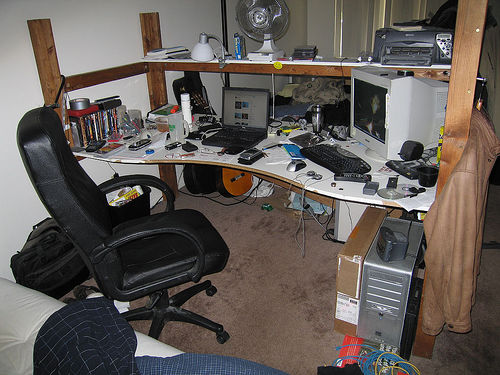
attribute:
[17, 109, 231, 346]
chair — black, leather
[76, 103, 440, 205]
desk — multileveled, white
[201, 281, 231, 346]
wheels — black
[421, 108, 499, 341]
brown jacket — hanging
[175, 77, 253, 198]
guitar — brown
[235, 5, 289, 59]
fan — white, small, silver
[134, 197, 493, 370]
carpet — brown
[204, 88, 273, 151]
laptop — open, small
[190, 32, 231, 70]
white lamp — clipped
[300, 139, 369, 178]
keyboard — black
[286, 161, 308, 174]
mouse — black, gray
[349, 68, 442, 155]
monitor — white, large, old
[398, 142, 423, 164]
speaker — black